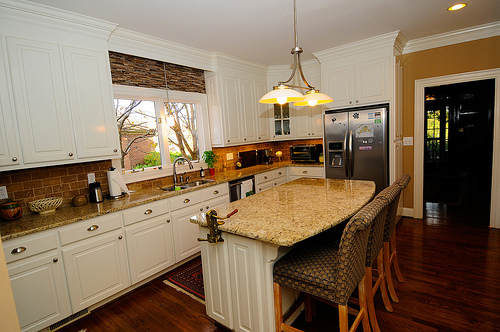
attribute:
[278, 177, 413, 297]
cushions — brown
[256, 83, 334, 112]
lights — white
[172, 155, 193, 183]
faucet — nickel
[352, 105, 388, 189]
fridge — steel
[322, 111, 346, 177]
freezer — steel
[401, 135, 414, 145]
light switch — white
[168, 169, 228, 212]
drawers — white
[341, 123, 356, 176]
handles — Brushed steel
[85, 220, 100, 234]
handle — Silver 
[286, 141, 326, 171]
toaster — black 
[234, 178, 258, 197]
towel — white 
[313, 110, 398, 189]
refrigerator — silver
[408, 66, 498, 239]
door frame — white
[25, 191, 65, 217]
basket — light brown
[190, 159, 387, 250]
table — yellow , white 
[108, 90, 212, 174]
windows — square , glass , wooden 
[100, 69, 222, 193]
frame — white 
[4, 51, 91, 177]
cabinets — white and wooden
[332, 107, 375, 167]
refrigerator — silver and metal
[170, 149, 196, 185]
faucet — silver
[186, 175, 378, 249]
counter top — tan, marble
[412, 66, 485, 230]
door way — open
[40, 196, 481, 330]
floor — dark brown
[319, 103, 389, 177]
refrigerator — silver, steel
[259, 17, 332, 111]
lights — hanging overhead